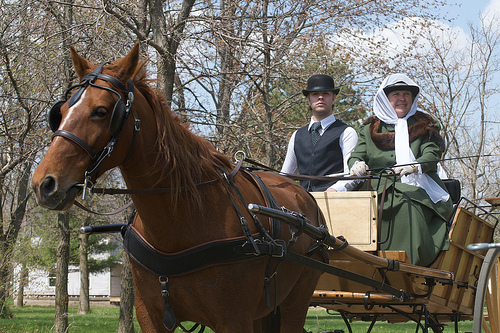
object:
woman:
[344, 71, 457, 273]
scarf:
[373, 72, 450, 203]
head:
[378, 78, 419, 117]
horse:
[29, 43, 330, 333]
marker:
[53, 88, 86, 144]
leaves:
[278, 52, 284, 56]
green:
[361, 143, 373, 153]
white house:
[11, 232, 127, 303]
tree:
[0, 0, 133, 321]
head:
[30, 41, 138, 211]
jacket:
[347, 116, 452, 266]